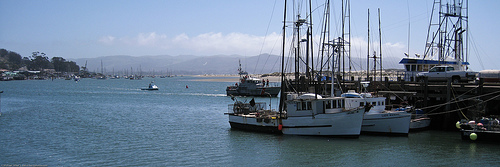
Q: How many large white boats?
A: 2.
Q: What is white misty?
A: Distant mountains.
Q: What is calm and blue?
A: Pleasant water.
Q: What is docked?
A: Nearby boats.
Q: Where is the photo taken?
A: Near the water.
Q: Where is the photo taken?
A: Near water.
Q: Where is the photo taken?
A: Near water.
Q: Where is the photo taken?
A: Near water.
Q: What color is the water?
A: Blue.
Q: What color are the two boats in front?
A: White.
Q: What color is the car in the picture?
A: White.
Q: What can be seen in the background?
A: Mountains.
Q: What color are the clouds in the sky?
A: White.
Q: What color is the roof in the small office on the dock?
A: Blue.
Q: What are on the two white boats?
A: Masts.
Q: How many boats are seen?
A: 2.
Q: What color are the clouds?
A: White.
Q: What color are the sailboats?
A: White.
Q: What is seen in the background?
A: Mountains.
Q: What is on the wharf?
A: A truck.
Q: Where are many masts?
A: On the boats.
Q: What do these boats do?
A: They are fishers.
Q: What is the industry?
A: Fishery.